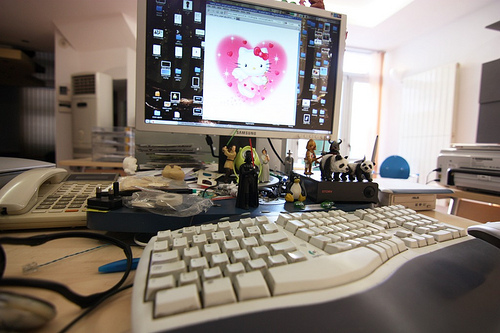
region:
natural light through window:
[298, 48, 382, 160]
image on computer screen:
[134, 1, 344, 136]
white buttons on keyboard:
[128, 201, 467, 331]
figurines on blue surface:
[218, 142, 374, 212]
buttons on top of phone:
[1, 165, 115, 228]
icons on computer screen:
[148, 0, 203, 117]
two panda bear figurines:
[322, 154, 373, 182]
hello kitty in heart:
[216, 33, 285, 105]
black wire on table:
[61, 284, 129, 331]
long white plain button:
[268, 247, 380, 294]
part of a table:
[478, 268, 480, 269]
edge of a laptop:
[343, 268, 345, 272]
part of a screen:
[286, 135, 293, 155]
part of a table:
[375, 230, 380, 235]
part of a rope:
[117, 280, 139, 307]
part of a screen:
[297, 90, 300, 112]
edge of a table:
[387, 323, 391, 331]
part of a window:
[408, 192, 410, 203]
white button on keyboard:
[233, 268, 269, 304]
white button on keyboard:
[200, 274, 232, 304]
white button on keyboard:
[151, 285, 204, 315]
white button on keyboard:
[144, 273, 174, 299]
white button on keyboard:
[176, 265, 201, 287]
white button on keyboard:
[199, 258, 220, 278]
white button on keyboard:
[221, 258, 247, 276]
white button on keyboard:
[244, 250, 266, 269]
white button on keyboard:
[266, 247, 286, 265]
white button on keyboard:
[286, 245, 301, 263]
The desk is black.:
[402, 283, 480, 320]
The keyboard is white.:
[141, 202, 474, 325]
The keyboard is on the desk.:
[129, 195, 476, 327]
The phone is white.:
[1, 162, 113, 231]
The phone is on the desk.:
[2, 162, 119, 229]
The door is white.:
[389, 57, 451, 139]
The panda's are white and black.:
[321, 153, 378, 180]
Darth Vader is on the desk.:
[235, 141, 263, 209]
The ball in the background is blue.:
[377, 153, 412, 178]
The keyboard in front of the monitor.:
[120, 198, 475, 313]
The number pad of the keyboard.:
[362, 200, 465, 241]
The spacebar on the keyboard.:
[270, 247, 380, 291]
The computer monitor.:
[137, 2, 344, 183]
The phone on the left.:
[7, 153, 102, 223]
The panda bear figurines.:
[321, 151, 376, 178]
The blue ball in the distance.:
[382, 157, 412, 177]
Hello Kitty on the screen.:
[215, 33, 287, 117]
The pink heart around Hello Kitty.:
[217, 33, 286, 113]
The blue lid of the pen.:
[94, 258, 141, 272]